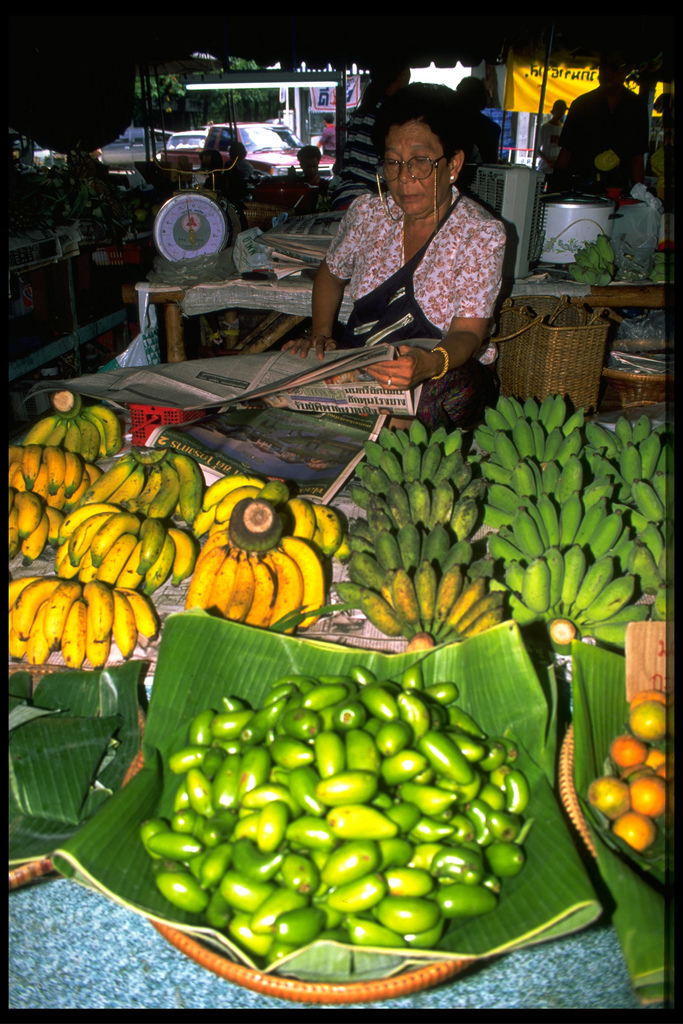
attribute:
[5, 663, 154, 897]
basket — brown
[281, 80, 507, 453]
woman — older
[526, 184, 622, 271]
crock pot — large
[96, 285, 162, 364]
bag — white, plastic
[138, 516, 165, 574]
banana — yellow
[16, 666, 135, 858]
leaves — green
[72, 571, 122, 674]
bananas — yellow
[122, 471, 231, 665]
bananas — yellow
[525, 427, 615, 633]
bananas — green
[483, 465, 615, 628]
bananas — green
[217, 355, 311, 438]
tag — red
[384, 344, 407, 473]
ring — silver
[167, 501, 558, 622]
bananas — yellow and green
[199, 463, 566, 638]
bananas — yellow and green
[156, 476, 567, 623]
bananas — yellow and green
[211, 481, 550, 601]
bananas — yellow and green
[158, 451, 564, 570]
bananas — yellow and green